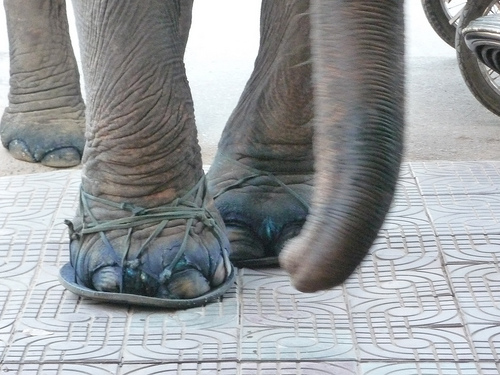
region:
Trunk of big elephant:
[275, 0, 403, 291]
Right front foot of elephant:
[56, 180, 236, 306]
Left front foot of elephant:
[205, 151, 311, 276]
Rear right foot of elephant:
[2, 108, 89, 173]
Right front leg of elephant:
[71, 0, 203, 198]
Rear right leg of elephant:
[0, 0, 80, 107]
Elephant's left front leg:
[225, 0, 316, 172]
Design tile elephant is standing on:
[5, 166, 496, 357]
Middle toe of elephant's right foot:
[161, 265, 209, 298]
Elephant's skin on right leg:
[88, 8, 188, 184]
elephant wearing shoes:
[11, 105, 439, 365]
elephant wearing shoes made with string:
[18, 76, 399, 371]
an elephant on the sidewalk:
[15, 8, 471, 370]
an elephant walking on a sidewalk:
[2, 6, 439, 374]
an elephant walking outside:
[12, 4, 479, 374]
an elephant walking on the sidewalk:
[12, 9, 499, 371]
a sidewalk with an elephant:
[5, 13, 494, 344]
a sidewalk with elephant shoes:
[4, 13, 413, 374]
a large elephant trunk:
[223, 18, 467, 374]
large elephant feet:
[54, 29, 358, 373]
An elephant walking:
[4, 0, 401, 300]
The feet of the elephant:
[5, 108, 312, 308]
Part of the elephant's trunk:
[278, 0, 408, 287]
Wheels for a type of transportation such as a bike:
[420, 0, 495, 117]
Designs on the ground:
[3, 173, 495, 371]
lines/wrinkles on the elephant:
[3, 4, 394, 290]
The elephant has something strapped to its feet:
[62, 188, 244, 306]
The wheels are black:
[425, 1, 495, 121]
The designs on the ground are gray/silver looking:
[13, 150, 499, 373]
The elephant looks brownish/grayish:
[6, 0, 410, 299]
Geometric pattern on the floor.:
[50, 327, 472, 361]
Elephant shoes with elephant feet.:
[57, 206, 246, 316]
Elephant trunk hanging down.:
[281, 10, 407, 295]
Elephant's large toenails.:
[9, 135, 83, 170]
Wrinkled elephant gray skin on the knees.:
[93, 19, 180, 186]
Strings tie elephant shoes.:
[84, 195, 214, 253]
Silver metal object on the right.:
[463, 3, 498, 119]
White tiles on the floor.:
[409, 166, 489, 338]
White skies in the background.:
[204, 9, 237, 96]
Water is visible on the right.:
[415, 60, 455, 130]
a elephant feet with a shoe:
[47, 186, 237, 321]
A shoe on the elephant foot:
[49, 218, 243, 316]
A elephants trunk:
[277, 32, 402, 303]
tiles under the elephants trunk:
[280, 242, 473, 364]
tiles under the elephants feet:
[50, 217, 241, 333]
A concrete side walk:
[415, 90, 475, 156]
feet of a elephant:
[2, 95, 343, 307]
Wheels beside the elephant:
[413, 0, 494, 130]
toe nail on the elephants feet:
[166, 266, 208, 298]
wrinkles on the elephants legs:
[70, 35, 206, 189]